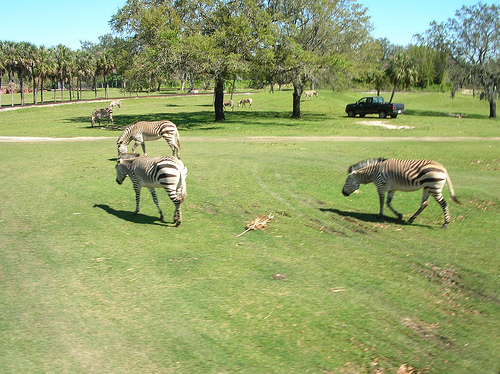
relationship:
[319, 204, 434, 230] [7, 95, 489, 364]
shadow on field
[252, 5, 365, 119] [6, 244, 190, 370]
tree on field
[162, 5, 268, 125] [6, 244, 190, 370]
tree on field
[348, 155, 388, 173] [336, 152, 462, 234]
mane on zebra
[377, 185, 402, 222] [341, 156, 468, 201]
legs are on zebra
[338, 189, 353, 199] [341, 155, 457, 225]
muzzle on zebra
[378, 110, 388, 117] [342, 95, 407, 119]
wheel on truck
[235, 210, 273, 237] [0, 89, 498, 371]
leaf on ground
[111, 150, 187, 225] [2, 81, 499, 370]
zebra walking on grass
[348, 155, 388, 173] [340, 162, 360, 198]
mane on head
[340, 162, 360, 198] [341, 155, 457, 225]
head on zebra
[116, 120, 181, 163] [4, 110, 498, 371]
zebra grazing in field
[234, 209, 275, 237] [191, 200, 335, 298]
leaf on ground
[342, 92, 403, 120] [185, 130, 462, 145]
truck parked across path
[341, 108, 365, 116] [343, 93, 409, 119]
wheels are on truck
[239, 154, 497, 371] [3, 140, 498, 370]
tire tracks are on grass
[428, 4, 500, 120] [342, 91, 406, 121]
trees in front of pickup truck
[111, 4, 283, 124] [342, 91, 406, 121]
trees in front of pickup truck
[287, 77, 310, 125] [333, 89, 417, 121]
tree trunk in front of truck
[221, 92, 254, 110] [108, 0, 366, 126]
two zebras are between two trees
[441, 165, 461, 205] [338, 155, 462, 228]
tail on zebra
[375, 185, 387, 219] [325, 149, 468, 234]
legs are on zebra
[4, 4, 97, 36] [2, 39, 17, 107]
sky above tree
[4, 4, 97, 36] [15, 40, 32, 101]
sky above tree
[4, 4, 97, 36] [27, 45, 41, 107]
sky above tree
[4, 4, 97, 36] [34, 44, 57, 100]
sky above tree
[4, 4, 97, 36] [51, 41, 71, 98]
sky above tree